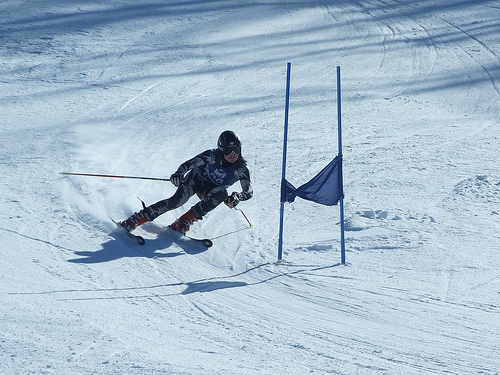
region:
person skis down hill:
[140, 143, 238, 255]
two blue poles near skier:
[251, 81, 375, 306]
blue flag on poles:
[307, 95, 357, 220]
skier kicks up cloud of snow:
[78, 115, 150, 257]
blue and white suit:
[145, 143, 243, 238]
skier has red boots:
[132, 213, 226, 243]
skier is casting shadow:
[94, 234, 185, 289]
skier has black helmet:
[207, 125, 265, 172]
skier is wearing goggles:
[222, 140, 246, 174]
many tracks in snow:
[101, 25, 375, 219]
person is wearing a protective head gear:
[116, 125, 256, 255]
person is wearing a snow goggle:
[99, 124, 258, 258]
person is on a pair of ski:
[72, 120, 257, 254]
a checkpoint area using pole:
[274, 58, 361, 279]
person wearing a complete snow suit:
[111, 122, 256, 257]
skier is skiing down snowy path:
[17, 17, 494, 357]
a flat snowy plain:
[347, 279, 498, 372]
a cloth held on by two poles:
[276, 148, 351, 212]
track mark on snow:
[335, 4, 498, 96]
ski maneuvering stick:
[59, 164, 192, 192]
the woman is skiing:
[59, 107, 279, 273]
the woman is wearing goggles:
[193, 105, 243, 165]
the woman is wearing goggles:
[192, 123, 258, 181]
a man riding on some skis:
[56, 126, 270, 271]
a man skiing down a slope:
[80, 124, 272, 269]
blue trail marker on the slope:
[268, 89, 360, 275]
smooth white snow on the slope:
[97, 306, 167, 356]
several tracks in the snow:
[333, 7, 492, 104]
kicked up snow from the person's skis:
[73, 129, 147, 208]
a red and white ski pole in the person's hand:
[56, 167, 178, 187]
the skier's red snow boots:
[111, 209, 202, 236]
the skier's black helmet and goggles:
[213, 127, 248, 155]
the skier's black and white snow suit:
[135, 155, 257, 230]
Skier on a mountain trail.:
[87, 122, 262, 263]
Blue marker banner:
[277, 167, 352, 213]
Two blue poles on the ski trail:
[274, 117, 347, 266]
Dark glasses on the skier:
[222, 143, 242, 157]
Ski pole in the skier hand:
[59, 164, 168, 187]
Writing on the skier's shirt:
[202, 154, 237, 190]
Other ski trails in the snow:
[342, 14, 497, 93]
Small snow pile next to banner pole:
[349, 205, 443, 237]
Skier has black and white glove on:
[166, 173, 188, 187]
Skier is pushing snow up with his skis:
[87, 197, 208, 263]